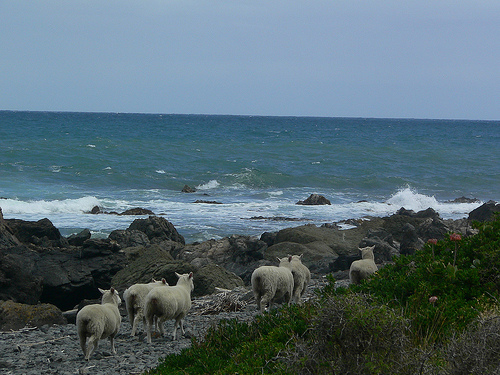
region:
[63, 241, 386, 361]
sheep on a trail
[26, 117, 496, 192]
ocean waters along a shore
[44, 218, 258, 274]
a rocky shore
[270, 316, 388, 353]
green grass along a trail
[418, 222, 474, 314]
flowers blooming along a trail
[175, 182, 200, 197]
rock in the water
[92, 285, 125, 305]
head os a sheep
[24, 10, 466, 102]
clear skys in the distance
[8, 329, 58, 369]
rocks on the trail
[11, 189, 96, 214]
waves in the ocean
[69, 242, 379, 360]
Sheep walking on a stony path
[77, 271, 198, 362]
Group of three white sheep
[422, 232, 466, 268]
Two red flowers on hill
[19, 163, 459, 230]
Ocean waves breaking on the rocks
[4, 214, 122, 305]
Wet gray rocks on shore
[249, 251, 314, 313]
Group of two white sheep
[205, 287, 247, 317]
Pile of sticks on path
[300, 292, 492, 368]
Green brush on hill side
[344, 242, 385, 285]
Single white sheep on path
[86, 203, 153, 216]
Gray rocks in the water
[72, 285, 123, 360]
a walking white sheep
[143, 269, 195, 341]
a walking white sheep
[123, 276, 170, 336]
a walking white sheep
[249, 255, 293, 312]
a walking white sheep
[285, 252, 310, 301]
a walking white sheep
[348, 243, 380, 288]
a walking white sheep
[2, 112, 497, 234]
a large body of water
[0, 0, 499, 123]
a hazy blue sky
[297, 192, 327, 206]
a large rock in water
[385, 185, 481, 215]
a white crashing wave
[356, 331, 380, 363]
part of a grass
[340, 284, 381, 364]
part of a grass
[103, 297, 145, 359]
poart of a oath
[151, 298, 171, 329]
part of a sheep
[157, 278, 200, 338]
part of a sheep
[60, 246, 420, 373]
group of sheep walking beside ocean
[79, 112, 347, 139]
calm surface of water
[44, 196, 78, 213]
waves covered in white sea foam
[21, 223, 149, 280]
large rocks on shore of water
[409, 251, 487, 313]
green bushes growing on shore of water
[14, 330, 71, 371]
ground covered in small grey rocks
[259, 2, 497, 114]
clear blue cloudless sky above water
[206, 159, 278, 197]
small wave on water surface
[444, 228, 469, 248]
small red flower bloom on plant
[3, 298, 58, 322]
green moss growing on top of rock